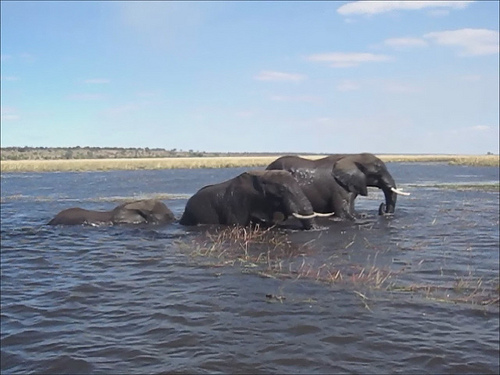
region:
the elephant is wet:
[152, 97, 473, 327]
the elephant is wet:
[95, 9, 405, 354]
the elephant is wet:
[172, 133, 383, 372]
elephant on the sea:
[171, 182, 358, 264]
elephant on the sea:
[121, 157, 408, 352]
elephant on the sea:
[61, 110, 325, 307]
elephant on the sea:
[144, 64, 336, 271]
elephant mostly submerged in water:
[47, 196, 178, 231]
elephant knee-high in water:
[265, 151, 410, 223]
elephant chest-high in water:
[180, 164, 332, 229]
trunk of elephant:
[374, 176, 397, 216]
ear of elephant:
[333, 155, 368, 202]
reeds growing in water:
[185, 226, 499, 304]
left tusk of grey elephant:
[290, 210, 317, 220]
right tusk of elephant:
[315, 211, 335, 221]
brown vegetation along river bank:
[0, 155, 492, 172]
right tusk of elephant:
[391, 186, 413, 198]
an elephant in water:
[46, 189, 194, 256]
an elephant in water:
[182, 169, 318, 242]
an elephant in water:
[258, 147, 418, 232]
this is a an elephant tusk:
[293, 209, 320, 225]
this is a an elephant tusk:
[309, 204, 336, 224]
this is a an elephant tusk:
[386, 182, 411, 208]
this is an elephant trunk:
[295, 196, 320, 241]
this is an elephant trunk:
[382, 179, 414, 229]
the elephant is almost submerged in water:
[46, 170, 189, 257]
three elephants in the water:
[38, 137, 420, 270]